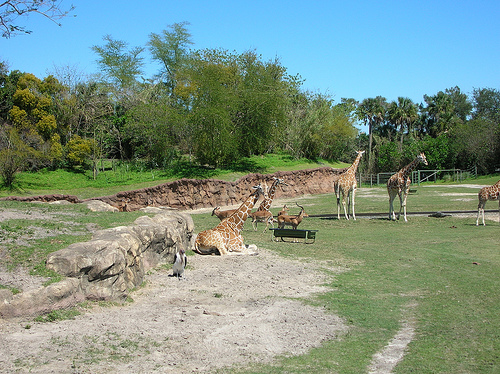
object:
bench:
[269, 228, 322, 243]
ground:
[0, 170, 500, 372]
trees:
[351, 93, 392, 178]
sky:
[0, 0, 499, 147]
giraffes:
[332, 149, 366, 220]